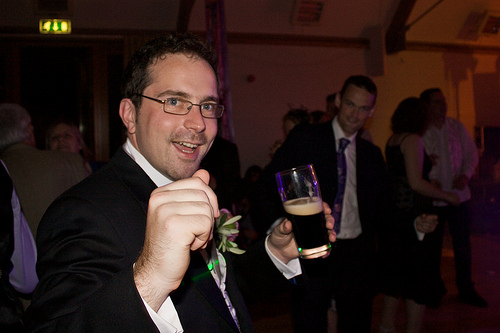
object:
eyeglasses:
[143, 93, 225, 119]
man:
[14, 25, 336, 332]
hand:
[143, 167, 225, 294]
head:
[335, 77, 379, 134]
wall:
[242, 44, 342, 101]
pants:
[288, 237, 377, 331]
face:
[138, 51, 220, 181]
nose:
[183, 105, 206, 132]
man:
[415, 86, 485, 308]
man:
[4, 101, 93, 233]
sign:
[35, 13, 79, 42]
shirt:
[324, 120, 364, 239]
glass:
[273, 163, 330, 259]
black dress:
[383, 129, 445, 307]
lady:
[377, 95, 460, 332]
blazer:
[19, 147, 297, 331]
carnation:
[218, 210, 246, 255]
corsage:
[204, 205, 250, 260]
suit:
[21, 137, 308, 331]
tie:
[332, 137, 349, 234]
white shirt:
[419, 119, 480, 204]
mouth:
[168, 134, 204, 159]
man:
[267, 78, 387, 332]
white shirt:
[4, 181, 40, 295]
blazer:
[267, 117, 388, 255]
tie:
[208, 242, 223, 281]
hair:
[127, 27, 221, 105]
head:
[126, 48, 226, 180]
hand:
[269, 197, 342, 258]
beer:
[283, 197, 329, 250]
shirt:
[122, 137, 244, 330]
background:
[227, 4, 496, 167]